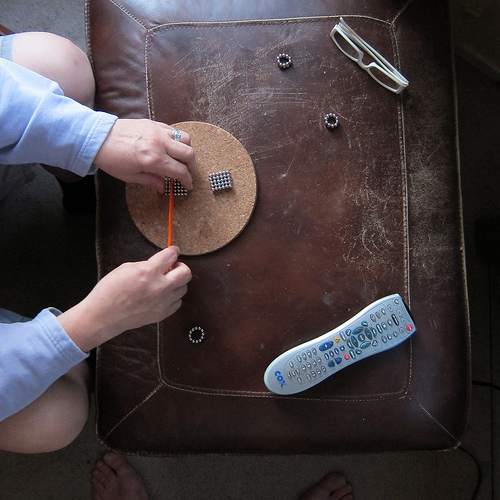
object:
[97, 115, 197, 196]
hand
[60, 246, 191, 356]
hand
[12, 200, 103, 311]
feet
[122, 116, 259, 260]
ceiling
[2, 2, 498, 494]
floor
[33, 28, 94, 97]
knee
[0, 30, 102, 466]
person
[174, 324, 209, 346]
ring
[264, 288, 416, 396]
remote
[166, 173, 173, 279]
device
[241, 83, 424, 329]
leather ottoman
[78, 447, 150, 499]
foot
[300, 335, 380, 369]
buttons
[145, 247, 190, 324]
fingers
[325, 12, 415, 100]
glasses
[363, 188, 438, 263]
old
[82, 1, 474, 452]
brown table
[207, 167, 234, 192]
object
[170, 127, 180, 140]
ring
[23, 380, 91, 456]
knee